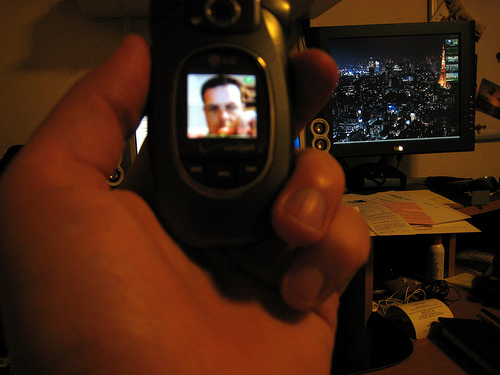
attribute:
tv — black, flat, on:
[278, 23, 482, 155]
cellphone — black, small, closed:
[150, 9, 300, 246]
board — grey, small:
[349, 165, 493, 208]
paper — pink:
[381, 192, 437, 235]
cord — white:
[372, 285, 435, 313]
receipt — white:
[363, 202, 402, 242]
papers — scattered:
[341, 188, 478, 244]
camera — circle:
[201, 3, 254, 34]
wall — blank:
[0, 5, 129, 95]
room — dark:
[1, 2, 499, 373]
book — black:
[432, 307, 499, 364]